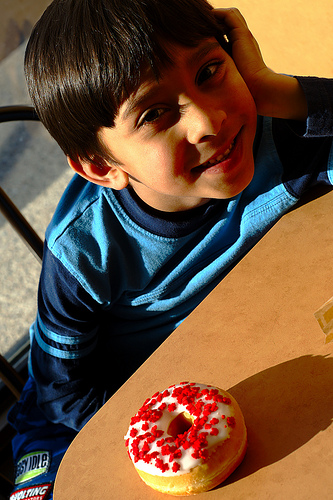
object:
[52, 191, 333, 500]
table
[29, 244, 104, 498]
hand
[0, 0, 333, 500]
boy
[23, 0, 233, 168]
hair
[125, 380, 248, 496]
doughnut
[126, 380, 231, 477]
cream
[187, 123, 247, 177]
mouth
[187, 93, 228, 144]
nose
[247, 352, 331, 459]
shade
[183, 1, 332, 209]
shade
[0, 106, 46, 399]
chair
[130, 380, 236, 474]
sprinkles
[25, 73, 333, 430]
shirt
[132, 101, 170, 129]
eye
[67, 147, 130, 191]
ear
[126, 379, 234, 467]
frosting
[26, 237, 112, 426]
sleeve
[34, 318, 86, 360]
stripe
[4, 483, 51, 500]
patch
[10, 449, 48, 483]
patch